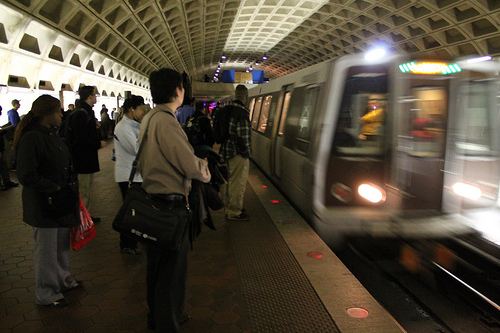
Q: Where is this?
A: This is at the train station.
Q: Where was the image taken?
A: It was taken at the train station.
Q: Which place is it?
A: It is a train station.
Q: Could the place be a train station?
A: Yes, it is a train station.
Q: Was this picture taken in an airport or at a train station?
A: It was taken at a train station.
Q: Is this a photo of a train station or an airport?
A: It is showing a train station.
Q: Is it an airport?
A: No, it is a train station.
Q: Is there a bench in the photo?
A: No, there are no benches.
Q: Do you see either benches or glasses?
A: No, there are no benches or glasses.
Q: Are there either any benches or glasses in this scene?
A: No, there are no benches or glasses.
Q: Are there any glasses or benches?
A: No, there are no benches or glasses.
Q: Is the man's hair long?
A: No, the hair is short.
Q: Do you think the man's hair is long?
A: No, the hair is short.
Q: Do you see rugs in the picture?
A: No, there are no rugs.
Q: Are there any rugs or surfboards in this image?
A: No, there are no rugs or surfboards.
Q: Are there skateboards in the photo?
A: No, there are no skateboards.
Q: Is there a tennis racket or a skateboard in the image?
A: No, there are no skateboards or rackets.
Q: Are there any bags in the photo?
A: Yes, there is a bag.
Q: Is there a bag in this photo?
A: Yes, there is a bag.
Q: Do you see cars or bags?
A: Yes, there is a bag.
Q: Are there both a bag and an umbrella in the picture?
A: No, there is a bag but no umbrellas.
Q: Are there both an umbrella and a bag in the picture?
A: No, there is a bag but no umbrellas.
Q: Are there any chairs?
A: No, there are no chairs.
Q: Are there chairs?
A: No, there are no chairs.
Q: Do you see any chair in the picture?
A: No, there are no chairs.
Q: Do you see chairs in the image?
A: No, there are no chairs.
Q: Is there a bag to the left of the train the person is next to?
A: Yes, there is a bag to the left of the train.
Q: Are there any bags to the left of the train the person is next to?
A: Yes, there is a bag to the left of the train.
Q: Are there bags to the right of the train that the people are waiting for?
A: No, the bag is to the left of the train.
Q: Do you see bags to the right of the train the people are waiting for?
A: No, the bag is to the left of the train.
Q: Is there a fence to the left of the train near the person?
A: No, there is a bag to the left of the train.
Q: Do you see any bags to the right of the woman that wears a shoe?
A: Yes, there is a bag to the right of the woman.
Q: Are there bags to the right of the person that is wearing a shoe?
A: Yes, there is a bag to the right of the woman.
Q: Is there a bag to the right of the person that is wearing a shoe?
A: Yes, there is a bag to the right of the woman.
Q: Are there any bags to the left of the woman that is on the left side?
A: No, the bag is to the right of the woman.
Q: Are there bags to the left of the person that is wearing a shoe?
A: No, the bag is to the right of the woman.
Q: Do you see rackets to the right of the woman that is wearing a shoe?
A: No, there is a bag to the right of the woman.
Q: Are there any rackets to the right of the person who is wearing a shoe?
A: No, there is a bag to the right of the woman.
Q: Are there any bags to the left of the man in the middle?
A: Yes, there is a bag to the left of the man.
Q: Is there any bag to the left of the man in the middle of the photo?
A: Yes, there is a bag to the left of the man.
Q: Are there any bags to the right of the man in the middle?
A: No, the bag is to the left of the man.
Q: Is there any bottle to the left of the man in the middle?
A: No, there is a bag to the left of the man.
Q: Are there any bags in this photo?
A: Yes, there is a bag.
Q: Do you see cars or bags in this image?
A: Yes, there is a bag.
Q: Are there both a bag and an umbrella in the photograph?
A: No, there is a bag but no umbrellas.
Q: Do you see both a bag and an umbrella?
A: No, there is a bag but no umbrellas.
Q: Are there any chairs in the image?
A: No, there are no chairs.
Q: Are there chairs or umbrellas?
A: No, there are no chairs or umbrellas.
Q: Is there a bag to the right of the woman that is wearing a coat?
A: Yes, there is a bag to the right of the woman.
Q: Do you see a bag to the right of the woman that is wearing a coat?
A: Yes, there is a bag to the right of the woman.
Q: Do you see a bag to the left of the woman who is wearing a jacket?
A: No, the bag is to the right of the woman.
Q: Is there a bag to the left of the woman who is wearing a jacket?
A: No, the bag is to the right of the woman.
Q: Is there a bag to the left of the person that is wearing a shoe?
A: No, the bag is to the right of the woman.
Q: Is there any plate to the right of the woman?
A: No, there is a bag to the right of the woman.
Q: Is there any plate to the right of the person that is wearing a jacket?
A: No, there is a bag to the right of the woman.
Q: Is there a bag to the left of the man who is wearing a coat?
A: Yes, there is a bag to the left of the man.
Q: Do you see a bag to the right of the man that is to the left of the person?
A: No, the bag is to the left of the man.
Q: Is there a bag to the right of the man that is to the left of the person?
A: No, the bag is to the left of the man.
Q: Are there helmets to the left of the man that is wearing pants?
A: No, there is a bag to the left of the man.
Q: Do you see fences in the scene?
A: No, there are no fences.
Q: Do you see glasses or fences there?
A: No, there are no fences or glasses.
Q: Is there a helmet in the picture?
A: No, there are no helmets.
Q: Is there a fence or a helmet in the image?
A: No, there are no helmets or fences.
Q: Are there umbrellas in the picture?
A: No, there are no umbrellas.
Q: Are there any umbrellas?
A: No, there are no umbrellas.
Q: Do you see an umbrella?
A: No, there are no umbrellas.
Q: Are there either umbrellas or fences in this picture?
A: No, there are no umbrellas or fences.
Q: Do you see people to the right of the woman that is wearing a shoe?
A: Yes, there are people to the right of the woman.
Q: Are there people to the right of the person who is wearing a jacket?
A: Yes, there are people to the right of the woman.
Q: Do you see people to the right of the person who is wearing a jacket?
A: Yes, there are people to the right of the woman.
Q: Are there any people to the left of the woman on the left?
A: No, the people are to the right of the woman.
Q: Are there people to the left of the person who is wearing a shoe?
A: No, the people are to the right of the woman.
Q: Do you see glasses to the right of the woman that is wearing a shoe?
A: No, there are people to the right of the woman.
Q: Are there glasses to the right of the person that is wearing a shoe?
A: No, there are people to the right of the woman.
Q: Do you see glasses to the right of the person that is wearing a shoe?
A: No, there are people to the right of the woman.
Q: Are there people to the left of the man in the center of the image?
A: Yes, there are people to the left of the man.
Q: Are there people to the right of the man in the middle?
A: No, the people are to the left of the man.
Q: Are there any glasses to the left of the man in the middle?
A: No, there are people to the left of the man.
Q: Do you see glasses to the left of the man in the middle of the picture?
A: No, there are people to the left of the man.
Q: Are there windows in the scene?
A: Yes, there is a window.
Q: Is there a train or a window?
A: Yes, there is a window.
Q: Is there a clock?
A: No, there are no clocks.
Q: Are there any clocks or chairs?
A: No, there are no clocks or chairs.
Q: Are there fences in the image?
A: No, there are no fences.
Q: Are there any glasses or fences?
A: No, there are no fences or glasses.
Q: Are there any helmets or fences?
A: No, there are no fences or helmets.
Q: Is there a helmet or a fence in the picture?
A: No, there are no fences or helmets.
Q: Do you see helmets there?
A: No, there are no helmets.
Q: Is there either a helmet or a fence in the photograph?
A: No, there are no helmets or fences.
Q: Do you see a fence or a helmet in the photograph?
A: No, there are no helmets or fences.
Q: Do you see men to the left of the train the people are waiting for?
A: Yes, there is a man to the left of the train.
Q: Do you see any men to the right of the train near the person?
A: No, the man is to the left of the train.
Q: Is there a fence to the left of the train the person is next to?
A: No, there is a man to the left of the train.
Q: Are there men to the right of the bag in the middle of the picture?
A: Yes, there is a man to the right of the bag.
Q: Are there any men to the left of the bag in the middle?
A: No, the man is to the right of the bag.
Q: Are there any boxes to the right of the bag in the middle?
A: No, there is a man to the right of the bag.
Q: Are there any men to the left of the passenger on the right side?
A: Yes, there is a man to the left of the passenger.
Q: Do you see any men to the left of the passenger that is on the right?
A: Yes, there is a man to the left of the passenger.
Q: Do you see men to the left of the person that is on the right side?
A: Yes, there is a man to the left of the passenger.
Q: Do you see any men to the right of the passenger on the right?
A: No, the man is to the left of the passenger.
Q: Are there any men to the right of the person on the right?
A: No, the man is to the left of the passenger.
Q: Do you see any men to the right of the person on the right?
A: No, the man is to the left of the passenger.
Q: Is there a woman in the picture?
A: Yes, there is a woman.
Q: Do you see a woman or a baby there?
A: Yes, there is a woman.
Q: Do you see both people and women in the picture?
A: Yes, there are both a woman and a person.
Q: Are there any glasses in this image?
A: No, there are no glasses.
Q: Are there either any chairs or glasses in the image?
A: No, there are no glasses or chairs.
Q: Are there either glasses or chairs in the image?
A: No, there are no glasses or chairs.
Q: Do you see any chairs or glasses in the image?
A: No, there are no glasses or chairs.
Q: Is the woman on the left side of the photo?
A: Yes, the woman is on the left of the image.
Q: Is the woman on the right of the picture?
A: No, the woman is on the left of the image.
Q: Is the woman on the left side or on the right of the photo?
A: The woman is on the left of the image.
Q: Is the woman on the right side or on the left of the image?
A: The woman is on the left of the image.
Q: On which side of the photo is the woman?
A: The woman is on the left of the image.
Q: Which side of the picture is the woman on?
A: The woman is on the left of the image.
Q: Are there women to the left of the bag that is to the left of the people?
A: Yes, there is a woman to the left of the bag.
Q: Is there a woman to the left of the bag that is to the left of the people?
A: Yes, there is a woman to the left of the bag.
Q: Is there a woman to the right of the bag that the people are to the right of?
A: No, the woman is to the left of the bag.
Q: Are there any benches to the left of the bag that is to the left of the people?
A: No, there is a woman to the left of the bag.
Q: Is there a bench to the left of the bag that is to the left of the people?
A: No, there is a woman to the left of the bag.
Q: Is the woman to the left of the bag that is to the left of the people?
A: Yes, the woman is to the left of the bag.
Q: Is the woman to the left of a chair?
A: No, the woman is to the left of the bag.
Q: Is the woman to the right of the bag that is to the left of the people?
A: No, the woman is to the left of the bag.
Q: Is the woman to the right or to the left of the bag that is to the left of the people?
A: The woman is to the left of the bag.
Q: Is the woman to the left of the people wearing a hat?
A: No, the woman is wearing a shoe.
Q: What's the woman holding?
A: The woman is holding the bag.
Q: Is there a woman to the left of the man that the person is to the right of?
A: Yes, there is a woman to the left of the man.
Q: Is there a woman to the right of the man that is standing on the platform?
A: No, the woman is to the left of the man.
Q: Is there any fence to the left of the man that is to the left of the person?
A: No, there is a woman to the left of the man.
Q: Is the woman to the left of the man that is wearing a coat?
A: Yes, the woman is to the left of the man.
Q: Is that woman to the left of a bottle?
A: No, the woman is to the left of the man.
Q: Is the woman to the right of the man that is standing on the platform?
A: No, the woman is to the left of the man.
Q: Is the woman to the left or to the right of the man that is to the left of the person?
A: The woman is to the left of the man.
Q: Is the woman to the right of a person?
A: No, the woman is to the left of a person.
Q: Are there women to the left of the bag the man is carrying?
A: Yes, there is a woman to the left of the bag.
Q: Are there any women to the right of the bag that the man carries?
A: No, the woman is to the left of the bag.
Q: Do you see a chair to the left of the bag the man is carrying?
A: No, there is a woman to the left of the bag.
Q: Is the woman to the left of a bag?
A: Yes, the woman is to the left of a bag.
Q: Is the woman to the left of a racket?
A: No, the woman is to the left of a bag.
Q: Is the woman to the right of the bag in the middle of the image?
A: No, the woman is to the left of the bag.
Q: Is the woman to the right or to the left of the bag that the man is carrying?
A: The woman is to the left of the bag.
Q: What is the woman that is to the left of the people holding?
A: The woman is holding the bag.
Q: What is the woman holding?
A: The woman is holding the bag.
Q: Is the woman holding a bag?
A: Yes, the woman is holding a bag.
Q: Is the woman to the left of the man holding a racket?
A: No, the woman is holding a bag.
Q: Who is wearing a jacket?
A: The woman is wearing a jacket.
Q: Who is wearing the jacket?
A: The woman is wearing a jacket.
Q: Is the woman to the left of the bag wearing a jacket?
A: Yes, the woman is wearing a jacket.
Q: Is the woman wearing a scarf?
A: No, the woman is wearing a jacket.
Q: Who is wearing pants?
A: The woman is wearing pants.